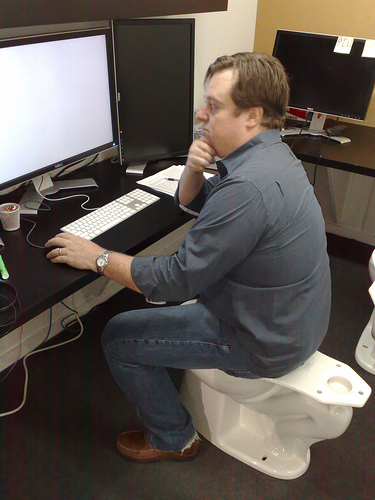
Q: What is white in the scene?
A: The toilet.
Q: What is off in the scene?
A: The computer monitor.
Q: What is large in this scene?
A: The computer monitor.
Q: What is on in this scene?
A: The computer monitor.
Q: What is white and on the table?
A: The keyboard.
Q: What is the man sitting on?
A: A porcelain toilet bowl.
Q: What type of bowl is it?
A: A porcelain toilet bowl.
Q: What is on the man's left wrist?
A: A watch.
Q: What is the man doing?
A: Using a computer.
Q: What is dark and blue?
A: The man's shirt.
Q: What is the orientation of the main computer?
A: Landscape.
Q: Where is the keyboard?
A: In front of the monitor.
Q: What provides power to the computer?
A: The grey electric wire.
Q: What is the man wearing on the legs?
A: Blue jeans.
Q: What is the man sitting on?
A: Bottom of a toilet.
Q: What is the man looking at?
A: Computer monitor?.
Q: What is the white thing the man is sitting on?
A: Toilet.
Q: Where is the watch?
A: Man's wrist.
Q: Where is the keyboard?
A: On desktop.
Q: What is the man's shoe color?
A: Brown.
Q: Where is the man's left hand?
A: On a computer mouse.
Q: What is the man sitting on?
A: A toilet.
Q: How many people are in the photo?
A: One.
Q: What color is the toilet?
A: White.